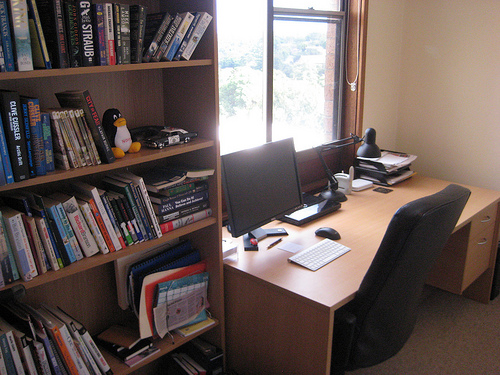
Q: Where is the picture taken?
A: An office.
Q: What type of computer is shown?
A: A desk top.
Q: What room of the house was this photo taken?
A: Office.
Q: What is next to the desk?
A: A bookshelf.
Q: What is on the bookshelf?
A: Books.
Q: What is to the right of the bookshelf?
A: A desk.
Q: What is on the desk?
A: A computer screen.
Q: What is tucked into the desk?
A: A desk chair.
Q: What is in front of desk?
A: A window.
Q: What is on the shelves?
A: Books.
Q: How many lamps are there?
A: One.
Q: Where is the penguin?
A: On the bookshelf.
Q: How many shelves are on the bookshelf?
A: Five.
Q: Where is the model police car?
A: Next to the penguin on the bookshelf.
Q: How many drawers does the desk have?
A: Two.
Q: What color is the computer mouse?
A: Black.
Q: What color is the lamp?
A: Black.